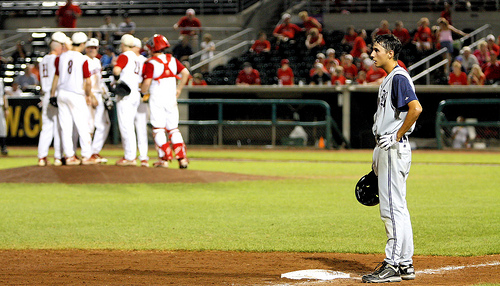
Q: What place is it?
A: It is a field.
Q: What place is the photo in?
A: It is at the field.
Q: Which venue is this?
A: This is a field.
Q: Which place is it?
A: It is a field.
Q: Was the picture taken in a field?
A: Yes, it was taken in a field.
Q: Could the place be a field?
A: Yes, it is a field.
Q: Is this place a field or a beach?
A: It is a field.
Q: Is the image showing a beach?
A: No, the picture is showing a field.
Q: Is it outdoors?
A: Yes, it is outdoors.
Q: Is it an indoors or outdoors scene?
A: It is outdoors.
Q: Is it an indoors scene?
A: No, it is outdoors.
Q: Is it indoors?
A: No, it is outdoors.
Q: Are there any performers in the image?
A: No, there are no performers.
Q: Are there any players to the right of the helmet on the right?
A: Yes, there is a player to the right of the helmet.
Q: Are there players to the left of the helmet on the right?
A: No, the player is to the right of the helmet.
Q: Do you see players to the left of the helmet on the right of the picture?
A: No, the player is to the right of the helmet.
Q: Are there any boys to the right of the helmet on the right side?
A: No, there is a player to the right of the helmet.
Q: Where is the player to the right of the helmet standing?
A: The player is standing in the field.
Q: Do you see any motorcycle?
A: No, there are no motorcycles.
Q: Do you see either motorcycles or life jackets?
A: No, there are no motorcycles or life jackets.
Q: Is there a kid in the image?
A: No, there are no children.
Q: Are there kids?
A: No, there are no kids.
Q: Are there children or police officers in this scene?
A: No, there are no children or police officers.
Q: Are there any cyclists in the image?
A: No, there are no cyclists.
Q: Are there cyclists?
A: No, there are no cyclists.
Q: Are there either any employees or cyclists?
A: No, there are no cyclists or employees.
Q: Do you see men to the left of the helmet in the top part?
A: Yes, there is a man to the left of the helmet.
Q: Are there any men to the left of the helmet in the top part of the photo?
A: Yes, there is a man to the left of the helmet.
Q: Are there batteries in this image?
A: No, there are no batteries.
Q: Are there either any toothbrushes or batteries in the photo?
A: No, there are no batteries or toothbrushes.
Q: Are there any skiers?
A: No, there are no skiers.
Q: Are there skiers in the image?
A: No, there are no skiers.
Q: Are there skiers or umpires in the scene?
A: No, there are no skiers or umpires.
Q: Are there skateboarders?
A: No, there are no skateboarders.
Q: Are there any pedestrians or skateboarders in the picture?
A: No, there are no skateboarders or pedestrians.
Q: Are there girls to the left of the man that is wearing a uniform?
A: No, there is a player to the left of the man.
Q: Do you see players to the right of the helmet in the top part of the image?
A: No, the player is to the left of the helmet.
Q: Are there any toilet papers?
A: No, there are no toilet papers.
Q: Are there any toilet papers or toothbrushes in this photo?
A: No, there are no toilet papers or toothbrushes.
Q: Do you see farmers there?
A: No, there are no farmers.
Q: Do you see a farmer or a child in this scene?
A: No, there are no farmers or children.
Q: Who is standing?
A: The player is standing.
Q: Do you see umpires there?
A: No, there are no umpires.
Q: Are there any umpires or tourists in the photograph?
A: No, there are no umpires or tourists.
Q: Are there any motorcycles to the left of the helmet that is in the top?
A: No, there is a player to the left of the helmet.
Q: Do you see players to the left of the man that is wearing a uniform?
A: Yes, there is a player to the left of the man.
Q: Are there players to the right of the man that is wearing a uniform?
A: No, the player is to the left of the man.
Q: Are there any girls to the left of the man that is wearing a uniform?
A: No, there is a player to the left of the man.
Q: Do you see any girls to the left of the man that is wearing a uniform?
A: No, there is a player to the left of the man.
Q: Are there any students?
A: No, there are no students.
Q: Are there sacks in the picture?
A: No, there are no sacks.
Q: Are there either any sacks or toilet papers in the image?
A: No, there are no sacks or toilet papers.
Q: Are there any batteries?
A: No, there are no batteries.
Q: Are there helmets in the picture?
A: Yes, there is a helmet.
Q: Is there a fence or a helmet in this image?
A: Yes, there is a helmet.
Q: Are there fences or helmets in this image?
A: Yes, there is a helmet.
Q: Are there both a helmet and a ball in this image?
A: No, there is a helmet but no balls.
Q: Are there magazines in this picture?
A: No, there are no magazines.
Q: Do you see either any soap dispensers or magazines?
A: No, there are no magazines or soap dispensers.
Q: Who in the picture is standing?
A: The player is standing.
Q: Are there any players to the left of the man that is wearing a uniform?
A: Yes, there is a player to the left of the man.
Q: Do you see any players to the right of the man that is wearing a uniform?
A: No, the player is to the left of the man.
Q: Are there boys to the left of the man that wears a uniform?
A: No, there is a player to the left of the man.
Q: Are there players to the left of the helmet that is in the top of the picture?
A: Yes, there is a player to the left of the helmet.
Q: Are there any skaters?
A: No, there are no skaters.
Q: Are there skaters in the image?
A: No, there are no skaters.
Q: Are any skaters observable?
A: No, there are no skaters.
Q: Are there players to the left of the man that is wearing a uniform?
A: Yes, there is a player to the left of the man.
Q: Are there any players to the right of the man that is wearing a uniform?
A: No, the player is to the left of the man.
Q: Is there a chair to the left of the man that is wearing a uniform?
A: No, there is a player to the left of the man.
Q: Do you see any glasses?
A: No, there are no glasses.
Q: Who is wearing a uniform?
A: The man is wearing a uniform.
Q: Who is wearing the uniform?
A: The man is wearing a uniform.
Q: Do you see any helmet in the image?
A: Yes, there is a helmet.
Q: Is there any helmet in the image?
A: Yes, there is a helmet.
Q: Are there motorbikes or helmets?
A: Yes, there is a helmet.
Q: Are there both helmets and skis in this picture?
A: No, there is a helmet but no skis.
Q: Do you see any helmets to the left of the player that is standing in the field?
A: Yes, there is a helmet to the left of the player.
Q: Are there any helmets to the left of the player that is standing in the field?
A: Yes, there is a helmet to the left of the player.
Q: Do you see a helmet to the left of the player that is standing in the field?
A: Yes, there is a helmet to the left of the player.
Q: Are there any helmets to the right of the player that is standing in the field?
A: No, the helmet is to the left of the player.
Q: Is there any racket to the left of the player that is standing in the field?
A: No, there is a helmet to the left of the player.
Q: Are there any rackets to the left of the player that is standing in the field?
A: No, there is a helmet to the left of the player.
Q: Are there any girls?
A: No, there are no girls.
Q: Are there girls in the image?
A: No, there are no girls.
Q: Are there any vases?
A: No, there are no vases.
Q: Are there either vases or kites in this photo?
A: No, there are no vases or kites.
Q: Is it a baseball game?
A: Yes, this is a baseball game.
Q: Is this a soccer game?
A: No, this is a baseball game.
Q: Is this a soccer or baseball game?
A: This is a baseball game.